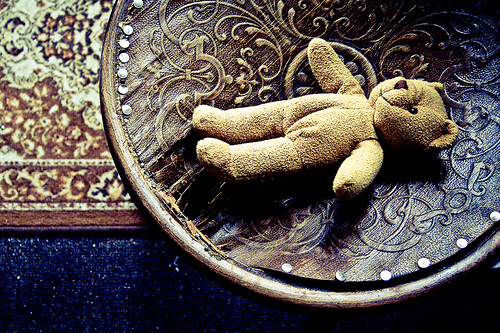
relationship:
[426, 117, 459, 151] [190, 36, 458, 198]
ear attached to bear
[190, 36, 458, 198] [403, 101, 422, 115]
bear has eye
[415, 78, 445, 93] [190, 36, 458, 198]
ear on bear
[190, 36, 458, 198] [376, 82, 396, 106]
bear has an mouth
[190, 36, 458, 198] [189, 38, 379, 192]
bear has body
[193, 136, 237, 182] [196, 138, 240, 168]
foot on bear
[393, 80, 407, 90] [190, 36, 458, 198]
nose on bear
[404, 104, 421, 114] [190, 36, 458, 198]
eye on bear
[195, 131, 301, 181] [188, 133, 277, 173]
leg on bears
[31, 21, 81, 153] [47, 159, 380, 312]
rug on floor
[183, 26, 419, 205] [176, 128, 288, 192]
bear has foot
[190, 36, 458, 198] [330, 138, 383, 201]
bear has left arm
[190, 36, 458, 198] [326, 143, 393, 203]
bear has left arm